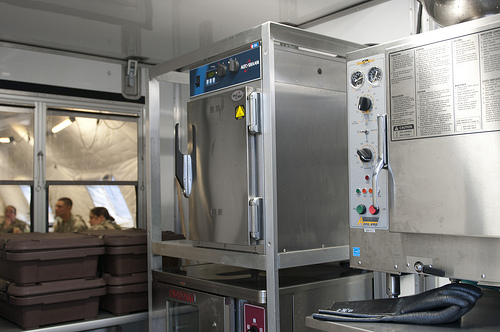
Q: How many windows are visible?
A: Two.